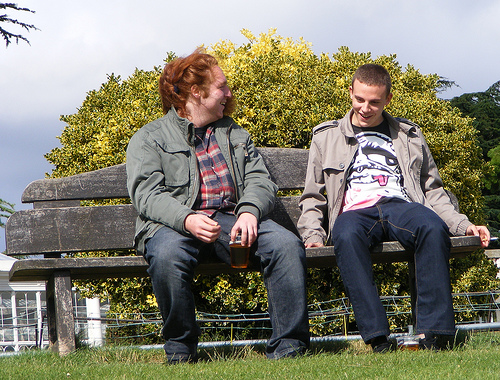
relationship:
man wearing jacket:
[295, 63, 490, 350] [296, 106, 473, 243]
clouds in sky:
[2, 0, 499, 142] [4, 2, 494, 165]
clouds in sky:
[2, 0, 499, 142] [0, 6, 499, 264]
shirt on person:
[164, 133, 229, 195] [123, 44, 309, 365]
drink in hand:
[230, 239, 252, 269] [177, 209, 219, 241]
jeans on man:
[331, 196, 462, 341] [295, 63, 490, 350]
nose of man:
[220, 80, 236, 104] [126, 41, 318, 374]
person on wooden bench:
[109, 47, 308, 358] [5, 147, 482, 352]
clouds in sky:
[2, 0, 499, 142] [0, 1, 68, 172]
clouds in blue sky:
[2, 0, 499, 142] [10, 117, 50, 182]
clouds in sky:
[2, 3, 498, 263] [389, 17, 496, 55]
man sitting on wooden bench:
[295, 63, 490, 354] [5, 147, 482, 352]